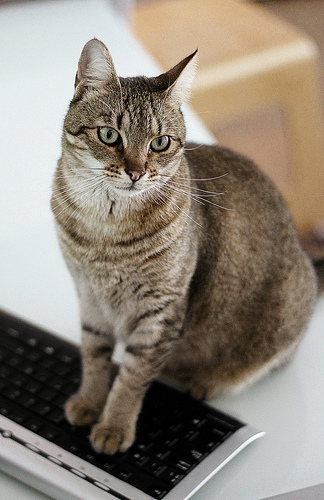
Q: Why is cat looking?
A: Photo.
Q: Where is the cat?
A: Table.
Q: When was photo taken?
A: Daytime.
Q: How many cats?
A: One.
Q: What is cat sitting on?
A: Table.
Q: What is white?
A: Table.